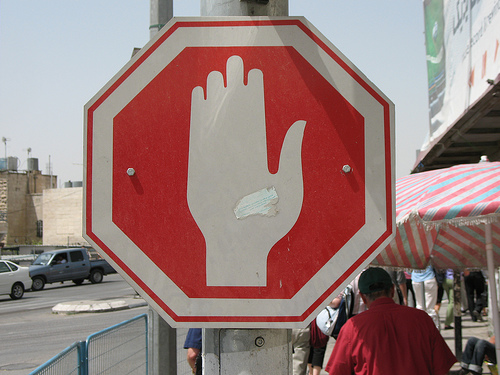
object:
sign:
[79, 16, 395, 329]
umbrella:
[370, 152, 499, 375]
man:
[325, 267, 454, 375]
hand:
[187, 53, 306, 287]